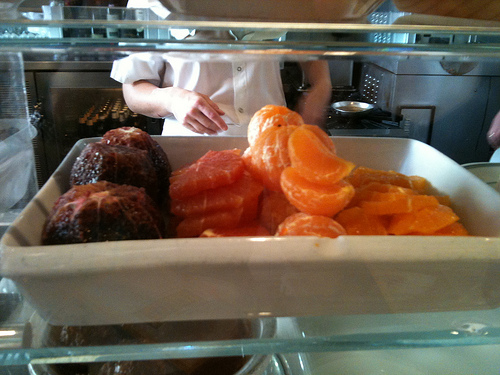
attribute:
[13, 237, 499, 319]
pan — plastic, white, shiny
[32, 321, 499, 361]
shelf — glass, clear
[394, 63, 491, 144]
appliance — steel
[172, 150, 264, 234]
grapefruit — sliced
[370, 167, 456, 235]
orange — sliced, peeled, piled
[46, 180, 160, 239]
fruit — dark, peeled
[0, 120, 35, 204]
tub — white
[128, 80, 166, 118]
arm — moving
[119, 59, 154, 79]
sleeve — rolled